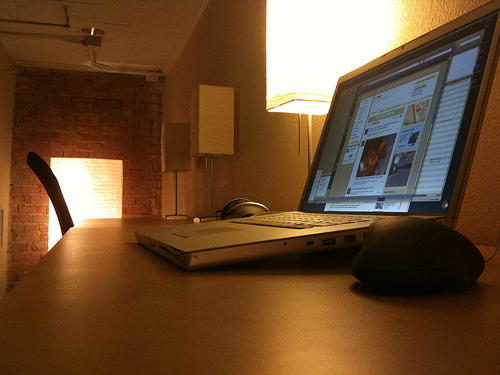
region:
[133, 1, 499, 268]
gray laptop on the table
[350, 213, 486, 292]
large black mouse on the table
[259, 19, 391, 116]
light on the wall lit up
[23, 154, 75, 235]
black chair at the desk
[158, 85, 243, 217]
two lights that are not on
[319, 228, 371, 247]
USB drives on the computer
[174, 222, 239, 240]
mousepad on the computer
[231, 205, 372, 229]
keyboard on the laptop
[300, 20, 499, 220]
powered on monitor for the laptop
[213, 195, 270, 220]
pair of gray headphones next to the laptop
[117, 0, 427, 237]
three lamps in a row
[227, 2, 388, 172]
lamp is powered on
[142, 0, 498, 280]
laptop is powered on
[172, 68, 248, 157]
lamp has white shade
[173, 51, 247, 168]
lamp shade is square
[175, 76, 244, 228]
lamp has pole base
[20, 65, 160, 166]
wall is made of brick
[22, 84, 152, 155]
brick wall is red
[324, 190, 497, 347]
black item on desk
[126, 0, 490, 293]
laptop is matte silver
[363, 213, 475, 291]
black computer mouse on desk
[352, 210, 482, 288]
black computer mouse on table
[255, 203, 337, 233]
keys on computer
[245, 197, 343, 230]
keys on front of lap top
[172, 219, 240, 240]
track pad on front of lap top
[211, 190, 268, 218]
mouse sitting on table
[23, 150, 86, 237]
back part of computer chair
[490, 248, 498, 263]
cord from mouse on deesk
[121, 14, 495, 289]
lap top and mouse on desk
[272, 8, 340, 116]
lamp shade lit up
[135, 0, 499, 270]
open laptop on top of a desk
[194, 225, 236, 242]
track pad on laptop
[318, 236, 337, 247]
usb port on side of laptop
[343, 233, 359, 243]
usb port next to usb port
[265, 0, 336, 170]
table lamp next to lap top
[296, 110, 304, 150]
pull chain hanging form table lamp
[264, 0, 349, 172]
table lamp is on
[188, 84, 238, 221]
table lamp is off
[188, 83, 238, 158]
rectangular lampshade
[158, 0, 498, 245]
wall behind laptop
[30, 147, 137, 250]
window in a room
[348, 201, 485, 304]
mouse on a table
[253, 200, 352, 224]
keys of a keyboard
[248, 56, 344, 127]
lamp by a laptop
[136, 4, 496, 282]
laptop on a table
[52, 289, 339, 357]
table where laptop is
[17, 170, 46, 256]
brick wall in a room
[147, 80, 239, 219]
two lamps on stands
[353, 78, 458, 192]
screen of a laptop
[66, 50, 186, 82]
poles on the ceiling